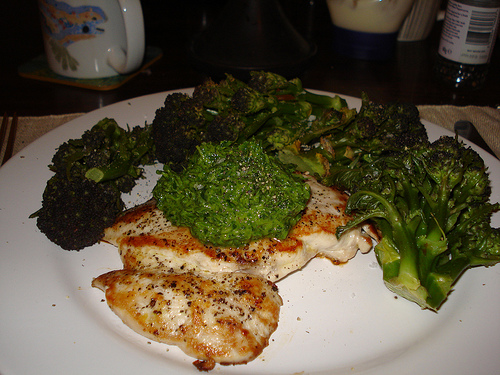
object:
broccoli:
[333, 129, 500, 317]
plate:
[1, 86, 500, 375]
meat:
[99, 172, 383, 285]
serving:
[0, 69, 500, 375]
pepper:
[430, 0, 499, 92]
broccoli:
[34, 172, 125, 253]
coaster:
[17, 42, 163, 92]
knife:
[452, 120, 500, 162]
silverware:
[0, 111, 9, 168]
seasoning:
[149, 298, 157, 308]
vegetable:
[320, 91, 431, 161]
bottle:
[321, 0, 413, 63]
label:
[437, 0, 500, 65]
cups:
[37, 0, 145, 81]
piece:
[242, 69, 351, 116]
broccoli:
[147, 75, 313, 173]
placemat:
[0, 104, 500, 167]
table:
[0, 0, 500, 375]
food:
[28, 68, 500, 374]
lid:
[328, 24, 402, 63]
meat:
[90, 269, 285, 373]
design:
[39, 0, 108, 73]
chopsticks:
[2, 111, 19, 170]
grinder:
[431, 0, 500, 93]